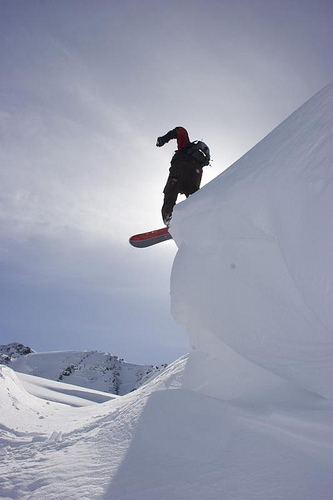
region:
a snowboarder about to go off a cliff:
[68, 100, 241, 273]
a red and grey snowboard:
[125, 224, 193, 255]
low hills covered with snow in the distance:
[12, 337, 164, 395]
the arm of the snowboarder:
[147, 124, 191, 147]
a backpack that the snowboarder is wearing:
[188, 140, 213, 166]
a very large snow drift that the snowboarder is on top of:
[169, 200, 323, 408]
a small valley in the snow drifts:
[17, 383, 111, 434]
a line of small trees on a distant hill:
[55, 351, 103, 388]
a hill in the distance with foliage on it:
[2, 338, 37, 367]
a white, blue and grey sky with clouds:
[8, 186, 110, 327]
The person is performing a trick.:
[101, 103, 238, 251]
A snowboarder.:
[22, 71, 311, 418]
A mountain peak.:
[5, 334, 156, 386]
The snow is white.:
[21, 414, 218, 474]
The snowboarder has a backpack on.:
[126, 121, 242, 259]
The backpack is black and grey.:
[184, 131, 211, 170]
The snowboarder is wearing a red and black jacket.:
[147, 115, 209, 240]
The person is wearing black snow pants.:
[109, 122, 222, 249]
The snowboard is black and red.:
[124, 225, 200, 254]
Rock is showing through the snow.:
[9, 332, 143, 380]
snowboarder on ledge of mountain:
[115, 117, 216, 249]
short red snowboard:
[123, 226, 176, 252]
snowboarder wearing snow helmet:
[126, 121, 221, 243]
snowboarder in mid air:
[116, 118, 211, 258]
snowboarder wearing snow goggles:
[95, 111, 230, 250]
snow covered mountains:
[3, 334, 205, 405]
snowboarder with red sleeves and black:
[75, 101, 249, 261]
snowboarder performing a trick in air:
[91, 110, 222, 249]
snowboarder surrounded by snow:
[113, 114, 241, 261]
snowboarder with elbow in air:
[111, 112, 219, 264]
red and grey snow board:
[129, 227, 179, 250]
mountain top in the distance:
[0, 339, 39, 367]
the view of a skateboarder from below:
[127, 120, 214, 248]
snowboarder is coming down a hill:
[125, 121, 213, 250]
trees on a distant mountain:
[52, 347, 126, 397]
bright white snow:
[1, 342, 201, 498]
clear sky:
[3, 0, 326, 366]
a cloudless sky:
[0, 2, 331, 371]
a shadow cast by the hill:
[106, 357, 331, 497]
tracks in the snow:
[1, 401, 115, 467]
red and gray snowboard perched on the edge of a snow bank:
[124, 223, 186, 251]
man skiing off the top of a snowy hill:
[145, 124, 211, 222]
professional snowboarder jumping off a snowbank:
[152, 125, 210, 223]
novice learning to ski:
[151, 122, 212, 229]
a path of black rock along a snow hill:
[108, 364, 125, 393]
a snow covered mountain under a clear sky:
[3, 338, 33, 365]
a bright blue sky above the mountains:
[24, 289, 148, 350]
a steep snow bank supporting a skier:
[169, 224, 212, 378]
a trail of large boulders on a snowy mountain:
[55, 351, 92, 382]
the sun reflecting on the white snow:
[40, 406, 138, 460]